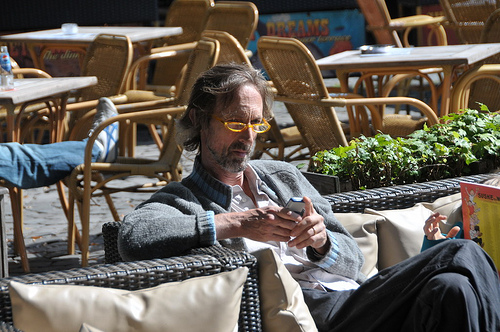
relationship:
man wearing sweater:
[117, 59, 500, 331] [114, 152, 363, 288]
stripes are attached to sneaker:
[94, 116, 118, 153] [82, 98, 126, 172]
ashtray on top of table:
[352, 38, 396, 58] [317, 29, 492, 116]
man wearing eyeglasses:
[117, 59, 500, 331] [216, 110, 269, 135]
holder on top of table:
[50, 14, 89, 39] [11, 17, 195, 77]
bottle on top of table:
[0, 38, 15, 92] [6, 51, 101, 142]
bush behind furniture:
[317, 86, 492, 185] [100, 173, 500, 267]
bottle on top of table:
[0, 44, 15, 92] [0, 61, 102, 161]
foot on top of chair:
[74, 91, 121, 167] [64, 41, 220, 243]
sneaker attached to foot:
[84, 92, 124, 173] [87, 102, 116, 172]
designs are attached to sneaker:
[87, 114, 119, 150] [83, 94, 125, 166]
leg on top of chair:
[3, 138, 100, 196] [30, 18, 227, 251]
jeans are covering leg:
[7, 133, 97, 196] [2, 123, 104, 201]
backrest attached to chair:
[84, 28, 137, 105] [74, 27, 130, 110]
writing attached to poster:
[264, 13, 357, 55] [251, 0, 366, 68]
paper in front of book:
[471, 192, 498, 265] [452, 170, 498, 260]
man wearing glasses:
[111, 59, 496, 326] [208, 114, 281, 137]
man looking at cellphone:
[111, 59, 496, 326] [278, 188, 306, 219]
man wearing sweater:
[111, 59, 496, 326] [114, 152, 363, 288]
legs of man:
[357, 222, 497, 330] [111, 59, 496, 326]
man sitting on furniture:
[111, 59, 496, 326] [0, 163, 493, 324]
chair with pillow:
[2, 245, 266, 330] [9, 270, 249, 328]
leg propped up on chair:
[0, 138, 100, 189] [56, 40, 227, 256]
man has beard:
[111, 59, 496, 326] [198, 119, 258, 172]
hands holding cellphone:
[252, 199, 325, 255] [278, 192, 305, 220]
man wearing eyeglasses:
[111, 59, 496, 326] [213, 119, 272, 133]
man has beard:
[111, 59, 496, 326] [208, 133, 259, 177]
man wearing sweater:
[111, 59, 496, 326] [109, 149, 366, 297]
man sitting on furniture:
[111, 59, 496, 326] [100, 173, 500, 267]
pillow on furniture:
[325, 210, 394, 270] [100, 173, 500, 267]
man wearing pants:
[111, 59, 496, 326] [320, 237, 494, 330]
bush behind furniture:
[294, 101, 499, 191] [100, 173, 500, 267]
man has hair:
[111, 59, 496, 326] [168, 60, 272, 171]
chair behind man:
[64, 38, 233, 221] [111, 59, 496, 326]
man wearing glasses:
[111, 59, 496, 326] [220, 116, 275, 136]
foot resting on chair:
[88, 96, 121, 164] [48, 33, 226, 248]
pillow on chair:
[5, 265, 256, 330] [2, 245, 266, 330]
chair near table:
[255, 32, 441, 155] [308, 37, 498, 78]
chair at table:
[255, 32, 441, 155] [308, 37, 498, 78]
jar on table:
[59, 19, 81, 37] [6, 16, 184, 59]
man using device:
[117, 59, 500, 331] [283, 194, 308, 216]